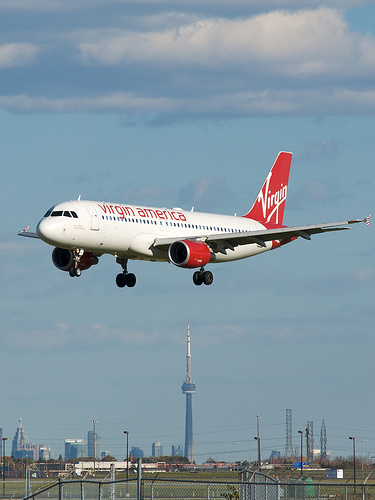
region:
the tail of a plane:
[238, 147, 295, 228]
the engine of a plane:
[164, 238, 215, 270]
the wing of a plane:
[144, 210, 374, 270]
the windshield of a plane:
[42, 208, 82, 220]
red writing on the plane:
[97, 199, 189, 221]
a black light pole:
[119, 426, 132, 478]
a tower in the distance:
[174, 320, 196, 463]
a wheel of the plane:
[110, 268, 138, 293]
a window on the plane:
[99, 212, 106, 221]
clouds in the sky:
[1, 0, 374, 134]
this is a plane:
[18, 147, 364, 301]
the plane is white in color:
[32, 152, 370, 282]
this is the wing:
[244, 211, 367, 259]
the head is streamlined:
[30, 196, 88, 249]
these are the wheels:
[190, 266, 219, 285]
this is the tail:
[246, 146, 303, 214]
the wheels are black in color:
[112, 269, 139, 289]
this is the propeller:
[165, 237, 212, 267]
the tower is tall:
[176, 321, 206, 450]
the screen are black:
[55, 210, 75, 217]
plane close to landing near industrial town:
[15, 145, 364, 482]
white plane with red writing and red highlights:
[37, 154, 337, 296]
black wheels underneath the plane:
[105, 245, 227, 301]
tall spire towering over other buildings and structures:
[167, 310, 205, 475]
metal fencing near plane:
[25, 444, 362, 494]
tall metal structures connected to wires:
[267, 390, 331, 465]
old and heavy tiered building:
[6, 412, 41, 458]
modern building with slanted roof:
[81, 420, 102, 461]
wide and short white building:
[60, 454, 165, 472]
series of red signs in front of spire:
[157, 456, 241, 473]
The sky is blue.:
[4, 3, 369, 320]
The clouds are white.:
[2, 2, 374, 119]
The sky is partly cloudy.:
[2, 0, 374, 161]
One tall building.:
[173, 313, 206, 461]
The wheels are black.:
[188, 267, 215, 285]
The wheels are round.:
[189, 266, 213, 286]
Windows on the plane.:
[95, 207, 261, 249]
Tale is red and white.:
[246, 145, 292, 233]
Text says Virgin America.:
[95, 197, 187, 224]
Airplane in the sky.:
[9, 145, 372, 289]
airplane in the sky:
[11, 131, 373, 294]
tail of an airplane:
[243, 141, 303, 229]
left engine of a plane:
[161, 236, 218, 270]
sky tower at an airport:
[175, 317, 207, 470]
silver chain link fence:
[50, 474, 235, 499]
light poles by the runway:
[341, 434, 365, 492]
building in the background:
[10, 419, 55, 463]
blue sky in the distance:
[35, 295, 339, 318]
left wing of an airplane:
[166, 210, 372, 261]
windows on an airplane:
[97, 211, 230, 232]